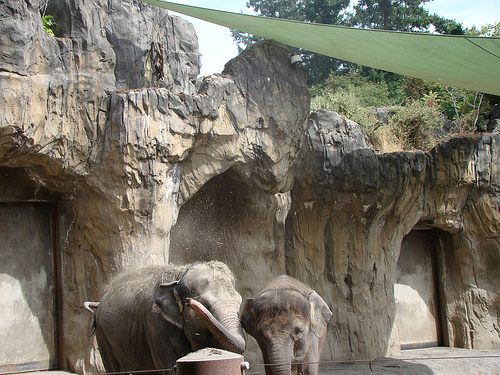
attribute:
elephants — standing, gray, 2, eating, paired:
[77, 257, 338, 374]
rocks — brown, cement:
[142, 105, 183, 138]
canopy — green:
[368, 41, 400, 66]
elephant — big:
[93, 279, 253, 360]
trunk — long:
[189, 297, 240, 344]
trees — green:
[366, 8, 391, 33]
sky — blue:
[445, 2, 482, 16]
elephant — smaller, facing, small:
[256, 266, 332, 375]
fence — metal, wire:
[354, 350, 475, 375]